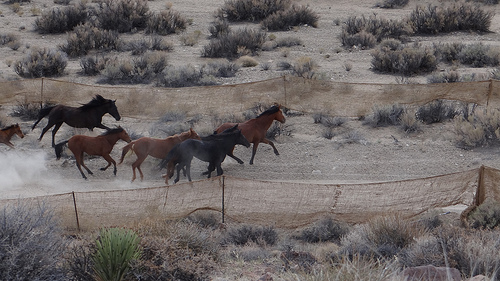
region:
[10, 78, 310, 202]
group of horses running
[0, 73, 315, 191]
horses running on trail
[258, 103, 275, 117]
black mane of horse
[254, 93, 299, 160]
large brown horse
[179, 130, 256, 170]
large black horse running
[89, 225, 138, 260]
green bush in the field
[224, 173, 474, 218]
orange fence on trail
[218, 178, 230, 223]
metal posts of fence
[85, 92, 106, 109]
black mane of horse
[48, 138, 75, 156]
black tail of horse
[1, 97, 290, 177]
a herd of running wild horses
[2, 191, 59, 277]
a gray dead brush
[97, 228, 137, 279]
wild green bush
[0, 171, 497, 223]
brown tarp fencing on a path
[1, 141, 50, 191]
dirt cloud kicked up by horses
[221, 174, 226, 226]
a metal fence post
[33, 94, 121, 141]
a black horse leaping into the air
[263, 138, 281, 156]
the lifted left front leg of a brown horse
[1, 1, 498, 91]
a bunch of gray bushes and dirt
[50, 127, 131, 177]
a running brown horse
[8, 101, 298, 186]
horses running down a road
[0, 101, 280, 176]
horses are kicking up dust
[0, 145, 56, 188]
dust that has been kicked up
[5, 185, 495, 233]
three fence posts with burlap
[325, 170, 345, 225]
a tear in the burlap from a missing post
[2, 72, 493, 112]
a burlap fabric fence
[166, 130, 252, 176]
a black horse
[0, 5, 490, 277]
a dry area with lots of shrubs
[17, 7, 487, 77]
lots of shrubs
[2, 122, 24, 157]
a small horse in the back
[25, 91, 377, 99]
horses free at run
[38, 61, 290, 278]
horses free at run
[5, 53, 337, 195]
horses free at run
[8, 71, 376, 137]
horses free at run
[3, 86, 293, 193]
horses running on a dirt track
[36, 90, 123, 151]
a black horse is running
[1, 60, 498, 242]
brown mesh fencing along the sides of a dirt track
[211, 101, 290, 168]
a brown horse is in the lead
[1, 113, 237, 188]
horse hooves are kicking up dust clouds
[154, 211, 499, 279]
dry brush alongside a mesh fence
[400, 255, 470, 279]
large brown rock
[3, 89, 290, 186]
horses are galloping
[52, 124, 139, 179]
brown horse with a black tail and mane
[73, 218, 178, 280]
a green shrub growing among some dry brush